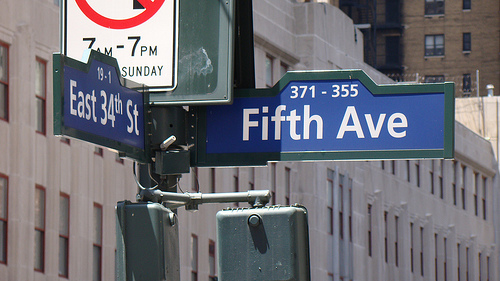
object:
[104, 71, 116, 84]
numbers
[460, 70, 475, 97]
sign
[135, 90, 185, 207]
pole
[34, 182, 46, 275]
windows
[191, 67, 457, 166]
blue sign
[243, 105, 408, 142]
fifth ave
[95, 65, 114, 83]
white print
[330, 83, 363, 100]
print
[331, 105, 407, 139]
print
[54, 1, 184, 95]
sign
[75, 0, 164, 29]
circle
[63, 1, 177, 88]
background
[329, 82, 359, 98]
355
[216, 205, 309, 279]
sign back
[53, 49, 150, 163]
sign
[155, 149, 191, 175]
boxes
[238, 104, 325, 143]
print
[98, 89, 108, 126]
white print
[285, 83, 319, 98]
371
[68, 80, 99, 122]
white print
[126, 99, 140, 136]
white print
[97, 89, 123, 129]
34th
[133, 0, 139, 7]
black print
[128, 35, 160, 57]
7pm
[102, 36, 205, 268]
post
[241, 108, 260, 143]
letter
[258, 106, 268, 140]
letter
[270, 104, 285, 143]
letter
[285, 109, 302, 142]
letter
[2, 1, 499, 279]
building